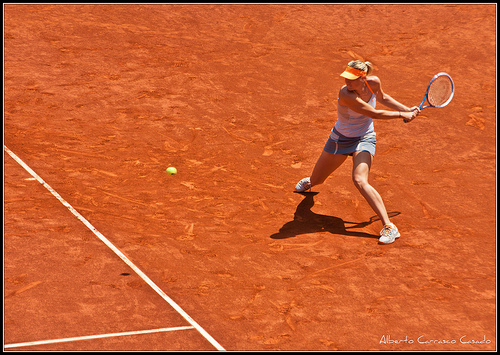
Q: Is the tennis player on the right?
A: Yes, the player is on the right of the image.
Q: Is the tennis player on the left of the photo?
A: No, the player is on the right of the image.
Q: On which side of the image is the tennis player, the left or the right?
A: The player is on the right of the image.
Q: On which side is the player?
A: The player is on the right of the image.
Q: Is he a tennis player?
A: Yes, that is a tennis player.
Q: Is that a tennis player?
A: Yes, that is a tennis player.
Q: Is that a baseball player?
A: No, that is a tennis player.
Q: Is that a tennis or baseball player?
A: That is a tennis player.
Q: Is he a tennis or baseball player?
A: That is a tennis player.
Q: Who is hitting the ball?
A: The player is hitting the ball.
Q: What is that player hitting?
A: The player is hitting the ball.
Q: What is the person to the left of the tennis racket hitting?
A: The player is hitting the ball.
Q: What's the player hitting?
A: The player is hitting the ball.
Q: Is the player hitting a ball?
A: Yes, the player is hitting a ball.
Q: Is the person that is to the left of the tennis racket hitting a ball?
A: Yes, the player is hitting a ball.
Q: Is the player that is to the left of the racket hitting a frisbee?
A: No, the player is hitting a ball.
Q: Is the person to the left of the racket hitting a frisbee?
A: No, the player is hitting a ball.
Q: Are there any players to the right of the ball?
A: Yes, there is a player to the right of the ball.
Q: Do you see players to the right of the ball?
A: Yes, there is a player to the right of the ball.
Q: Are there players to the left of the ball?
A: No, the player is to the right of the ball.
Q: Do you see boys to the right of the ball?
A: No, there is a player to the right of the ball.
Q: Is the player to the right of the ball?
A: Yes, the player is to the right of the ball.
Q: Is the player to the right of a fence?
A: No, the player is to the right of the ball.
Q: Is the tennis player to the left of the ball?
A: No, the player is to the right of the ball.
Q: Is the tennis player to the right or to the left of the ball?
A: The player is to the right of the ball.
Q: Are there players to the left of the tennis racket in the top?
A: Yes, there is a player to the left of the tennis racket.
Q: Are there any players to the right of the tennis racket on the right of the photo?
A: No, the player is to the left of the racket.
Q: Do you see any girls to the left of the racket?
A: No, there is a player to the left of the racket.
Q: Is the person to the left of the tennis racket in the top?
A: Yes, the player is to the left of the racket.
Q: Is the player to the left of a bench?
A: No, the player is to the left of the racket.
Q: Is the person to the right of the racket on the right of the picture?
A: No, the player is to the left of the tennis racket.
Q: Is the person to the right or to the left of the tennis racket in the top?
A: The player is to the left of the tennis racket.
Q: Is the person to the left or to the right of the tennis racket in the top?
A: The player is to the left of the tennis racket.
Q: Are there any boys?
A: No, there are no boys.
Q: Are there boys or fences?
A: No, there are no boys or fences.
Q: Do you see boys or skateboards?
A: No, there are no boys or skateboards.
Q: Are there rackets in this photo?
A: Yes, there is a racket.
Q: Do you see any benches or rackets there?
A: Yes, there is a racket.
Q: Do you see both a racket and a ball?
A: Yes, there are both a racket and a ball.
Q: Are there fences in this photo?
A: No, there are no fences.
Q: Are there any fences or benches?
A: No, there are no fences or benches.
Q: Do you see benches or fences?
A: No, there are no fences or benches.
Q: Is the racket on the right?
A: Yes, the racket is on the right of the image.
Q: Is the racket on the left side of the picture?
A: No, the racket is on the right of the image.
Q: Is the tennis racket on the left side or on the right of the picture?
A: The tennis racket is on the right of the image.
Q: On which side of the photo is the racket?
A: The racket is on the right of the image.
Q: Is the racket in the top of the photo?
A: Yes, the racket is in the top of the image.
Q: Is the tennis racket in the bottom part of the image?
A: No, the tennis racket is in the top of the image.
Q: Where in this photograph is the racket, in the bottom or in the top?
A: The racket is in the top of the image.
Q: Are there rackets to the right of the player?
A: Yes, there is a racket to the right of the player.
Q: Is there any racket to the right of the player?
A: Yes, there is a racket to the right of the player.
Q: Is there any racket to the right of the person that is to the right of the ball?
A: Yes, there is a racket to the right of the player.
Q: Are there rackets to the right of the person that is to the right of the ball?
A: Yes, there is a racket to the right of the player.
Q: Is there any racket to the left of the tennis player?
A: No, the racket is to the right of the player.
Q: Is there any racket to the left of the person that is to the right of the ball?
A: No, the racket is to the right of the player.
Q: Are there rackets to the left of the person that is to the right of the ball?
A: No, the racket is to the right of the player.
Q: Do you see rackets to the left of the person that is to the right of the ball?
A: No, the racket is to the right of the player.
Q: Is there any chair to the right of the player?
A: No, there is a racket to the right of the player.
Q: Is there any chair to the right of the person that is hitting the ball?
A: No, there is a racket to the right of the player.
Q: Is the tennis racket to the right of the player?
A: Yes, the tennis racket is to the right of the player.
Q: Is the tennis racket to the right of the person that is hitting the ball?
A: Yes, the tennis racket is to the right of the player.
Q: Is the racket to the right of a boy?
A: No, the racket is to the right of the player.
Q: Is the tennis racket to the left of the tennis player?
A: No, the tennis racket is to the right of the player.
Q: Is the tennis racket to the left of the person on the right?
A: No, the tennis racket is to the right of the player.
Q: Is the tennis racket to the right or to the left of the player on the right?
A: The tennis racket is to the right of the player.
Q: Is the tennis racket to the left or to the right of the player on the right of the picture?
A: The tennis racket is to the right of the player.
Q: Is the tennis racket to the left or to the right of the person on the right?
A: The tennis racket is to the right of the player.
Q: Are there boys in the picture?
A: No, there are no boys.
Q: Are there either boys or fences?
A: No, there are no boys or fences.